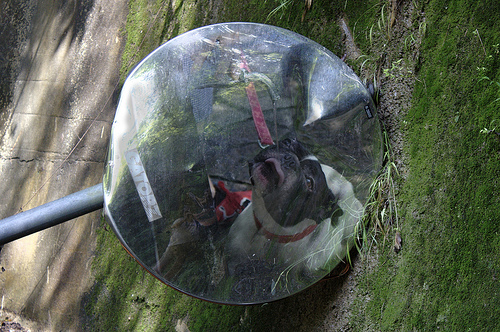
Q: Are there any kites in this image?
A: No, there are no kites.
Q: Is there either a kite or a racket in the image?
A: No, there are no kites or rackets.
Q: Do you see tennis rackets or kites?
A: No, there are no kites or tennis rackets.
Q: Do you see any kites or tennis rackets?
A: No, there are no kites or tennis rackets.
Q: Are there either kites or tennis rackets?
A: No, there are no kites or tennis rackets.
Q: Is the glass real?
A: Yes, the glass is real.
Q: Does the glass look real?
A: Yes, the glass is real.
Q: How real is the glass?
A: The glass is real.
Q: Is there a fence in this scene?
A: No, there are no fences.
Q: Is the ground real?
A: Yes, the ground is real.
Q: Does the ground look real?
A: Yes, the ground is real.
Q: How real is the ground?
A: The ground is real.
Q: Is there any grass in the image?
A: Yes, there is grass.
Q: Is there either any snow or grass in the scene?
A: Yes, there is grass.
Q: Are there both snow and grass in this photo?
A: No, there is grass but no snow.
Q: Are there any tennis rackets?
A: No, there are no tennis rackets.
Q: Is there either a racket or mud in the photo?
A: No, there are no rackets or mud.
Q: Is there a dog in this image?
A: Yes, there is a dog.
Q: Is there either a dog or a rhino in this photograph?
A: Yes, there is a dog.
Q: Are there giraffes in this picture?
A: No, there are no giraffes.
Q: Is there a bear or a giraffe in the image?
A: No, there are no giraffes or bears.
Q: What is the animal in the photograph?
A: The animal is a dog.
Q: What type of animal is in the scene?
A: The animal is a dog.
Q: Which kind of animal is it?
A: The animal is a dog.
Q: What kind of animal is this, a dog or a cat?
A: This is a dog.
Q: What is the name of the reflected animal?
A: The animal is a dog.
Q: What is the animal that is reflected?
A: The animal is a dog.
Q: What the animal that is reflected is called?
A: The animal is a dog.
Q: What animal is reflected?
A: The animal is a dog.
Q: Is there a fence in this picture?
A: No, there are no fences.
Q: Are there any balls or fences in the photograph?
A: No, there are no fences or balls.